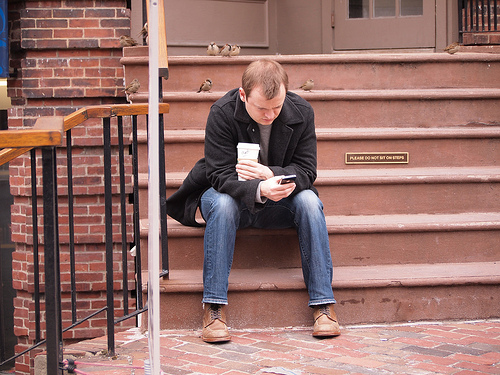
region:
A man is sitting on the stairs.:
[160, 26, 395, 357]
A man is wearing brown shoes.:
[175, 285, 385, 345]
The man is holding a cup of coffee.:
[230, 136, 260, 192]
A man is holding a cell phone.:
[265, 160, 303, 195]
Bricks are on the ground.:
[245, 340, 477, 371]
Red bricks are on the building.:
[15, 90, 122, 341]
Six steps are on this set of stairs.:
[346, 45, 491, 351]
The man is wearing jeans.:
[181, 175, 347, 308]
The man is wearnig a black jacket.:
[151, 61, 323, 237]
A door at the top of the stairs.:
[322, 0, 453, 52]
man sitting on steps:
[198, 66, 349, 348]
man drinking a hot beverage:
[202, 64, 333, 268]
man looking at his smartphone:
[211, 66, 331, 253]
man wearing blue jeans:
[187, 61, 344, 328]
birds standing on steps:
[173, 24, 247, 102]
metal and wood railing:
[12, 98, 143, 368]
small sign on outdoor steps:
[338, 121, 426, 198]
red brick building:
[21, 18, 141, 330]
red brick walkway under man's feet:
[176, 327, 421, 372]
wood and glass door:
[305, 0, 450, 56]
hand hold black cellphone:
[260, 172, 315, 202]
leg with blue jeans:
[191, 189, 245, 349]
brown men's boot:
[197, 295, 249, 347]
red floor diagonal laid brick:
[368, 327, 483, 370]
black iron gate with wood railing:
[24, 98, 138, 369]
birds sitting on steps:
[193, 27, 250, 66]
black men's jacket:
[172, 89, 329, 231]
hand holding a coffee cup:
[233, 137, 273, 187]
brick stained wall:
[30, 14, 95, 90]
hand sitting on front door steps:
[184, 57, 483, 345]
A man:
[128, 47, 392, 360]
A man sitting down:
[166, 56, 365, 364]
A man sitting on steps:
[172, 36, 374, 355]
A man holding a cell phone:
[180, 40, 372, 366]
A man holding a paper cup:
[174, 48, 395, 372]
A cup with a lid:
[209, 136, 285, 198]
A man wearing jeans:
[198, 57, 347, 345]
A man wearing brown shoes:
[166, 53, 352, 359]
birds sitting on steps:
[195, 28, 255, 108]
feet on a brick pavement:
[166, 316, 412, 374]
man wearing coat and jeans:
[171, 62, 361, 345]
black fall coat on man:
[166, 91, 343, 225]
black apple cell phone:
[249, 168, 301, 207]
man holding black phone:
[167, 66, 354, 346]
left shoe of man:
[193, 308, 235, 350]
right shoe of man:
[306, 303, 343, 346]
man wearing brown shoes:
[185, 57, 346, 339]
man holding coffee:
[171, 36, 368, 343]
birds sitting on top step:
[188, 22, 270, 62]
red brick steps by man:
[286, 311, 456, 368]